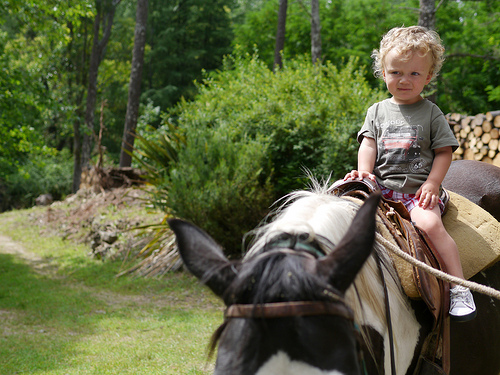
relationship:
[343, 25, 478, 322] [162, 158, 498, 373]
boy riding horse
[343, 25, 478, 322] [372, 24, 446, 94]
boy with curly hair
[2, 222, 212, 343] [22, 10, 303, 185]
path in woods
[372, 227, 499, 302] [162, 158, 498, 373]
beige rope attached horse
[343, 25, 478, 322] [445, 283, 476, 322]
boy wearing shoes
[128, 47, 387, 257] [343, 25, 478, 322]
bush behind boy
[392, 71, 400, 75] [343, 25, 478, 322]
child eyes of boy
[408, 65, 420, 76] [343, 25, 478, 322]
eye of boy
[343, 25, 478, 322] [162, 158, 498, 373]
boy on horse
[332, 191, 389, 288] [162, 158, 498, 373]
ear on horse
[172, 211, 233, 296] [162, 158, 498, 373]
ear on horse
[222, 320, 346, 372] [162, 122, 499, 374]
face on horse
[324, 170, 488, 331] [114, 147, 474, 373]
saddle on horse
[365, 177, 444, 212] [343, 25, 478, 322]
short on boy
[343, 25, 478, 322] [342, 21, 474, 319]
boy sitting on horse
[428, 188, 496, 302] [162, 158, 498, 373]
blanket on horse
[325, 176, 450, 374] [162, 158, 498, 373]
saddle on horse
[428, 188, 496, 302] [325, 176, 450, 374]
blanket under saddle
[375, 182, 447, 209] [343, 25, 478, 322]
shorts on boy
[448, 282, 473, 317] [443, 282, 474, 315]
shoe on foot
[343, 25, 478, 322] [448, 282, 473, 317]
boy wearing a shoe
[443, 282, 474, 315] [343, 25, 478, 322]
foot on boy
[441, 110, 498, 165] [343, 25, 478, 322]
wood behind boy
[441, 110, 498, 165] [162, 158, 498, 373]
wood behind horse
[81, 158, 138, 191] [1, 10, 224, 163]
trunk of trees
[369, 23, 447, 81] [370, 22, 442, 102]
curly hair of head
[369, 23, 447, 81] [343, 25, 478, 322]
curly hair of boy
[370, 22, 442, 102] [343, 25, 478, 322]
head of boy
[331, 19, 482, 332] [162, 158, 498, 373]
boy sitting on horse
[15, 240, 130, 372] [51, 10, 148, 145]
shadow of tree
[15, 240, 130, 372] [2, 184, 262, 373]
shadow on ground